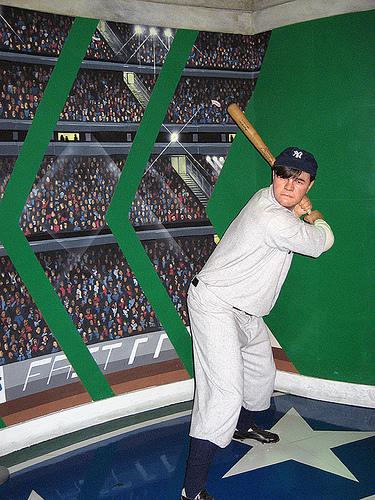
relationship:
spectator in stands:
[91, 274, 113, 292] [89, 278, 124, 310]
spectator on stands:
[67, 206, 80, 223] [41, 185, 94, 231]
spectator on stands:
[104, 292, 113, 302] [49, 247, 159, 338]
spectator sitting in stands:
[177, 192, 182, 203] [0, 10, 270, 375]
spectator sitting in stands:
[0, 8, 265, 366] [110, 302, 118, 316]